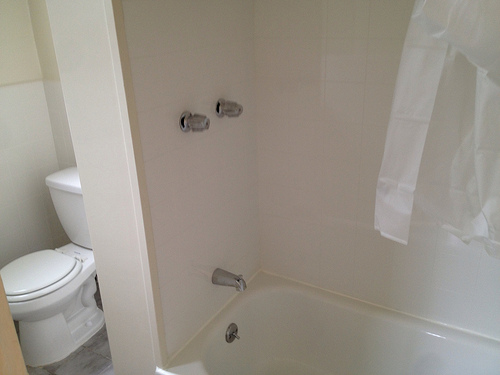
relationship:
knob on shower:
[211, 92, 251, 125] [112, 2, 498, 372]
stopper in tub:
[222, 320, 247, 345] [155, 272, 497, 372]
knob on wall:
[179, 107, 214, 131] [114, 5, 256, 364]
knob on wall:
[211, 95, 242, 119] [114, 5, 256, 364]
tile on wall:
[16, 75, 106, 242] [151, 9, 498, 369]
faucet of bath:
[212, 268, 249, 290] [162, 269, 498, 372]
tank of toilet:
[47, 164, 92, 252] [0, 238, 100, 368]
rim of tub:
[322, 291, 361, 308] [215, 290, 366, 373]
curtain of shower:
[365, 20, 499, 280] [112, 2, 498, 372]